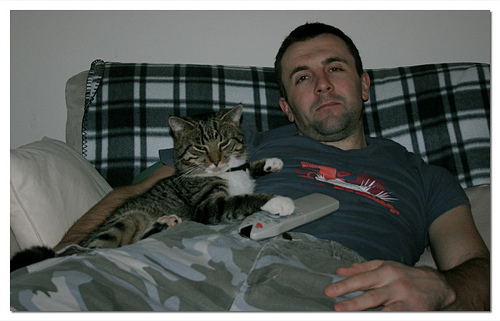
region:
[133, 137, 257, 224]
black and white cat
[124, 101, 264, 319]
a cat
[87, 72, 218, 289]
a cat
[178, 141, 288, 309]
a cat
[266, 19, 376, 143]
the head of a man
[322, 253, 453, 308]
the hand of a man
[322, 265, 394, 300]
the finger of a man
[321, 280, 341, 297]
the finger nail of a man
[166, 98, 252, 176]
the head of a cat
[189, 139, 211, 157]
the eye of a cat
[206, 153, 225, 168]
the nose of a cat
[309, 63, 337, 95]
the nose of a man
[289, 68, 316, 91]
the eye of a man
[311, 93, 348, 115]
the mouth of a man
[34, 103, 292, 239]
the striped cat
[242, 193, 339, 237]
the gray remote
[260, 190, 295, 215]
the cat paw on the remote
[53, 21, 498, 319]
the man on the couch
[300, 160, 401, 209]
the design on the man's shirt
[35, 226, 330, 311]
the man's camouflage pants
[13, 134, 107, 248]
the white pillow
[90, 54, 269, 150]
the striped blanket on the couch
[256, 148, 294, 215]
the cat's front paws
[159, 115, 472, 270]
the man's short sleeved shirt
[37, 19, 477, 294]
The man is lying down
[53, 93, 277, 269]
The cat is lying down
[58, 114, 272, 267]
The cat is striped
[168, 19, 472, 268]
The man is wearing a black shirt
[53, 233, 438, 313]
The man is wearing camo pants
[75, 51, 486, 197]
The blanket is black and white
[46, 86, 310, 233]
The cat is lying on top of the man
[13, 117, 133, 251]
The pillow is white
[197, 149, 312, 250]
The cat has white paws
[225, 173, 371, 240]
The remote control is grey